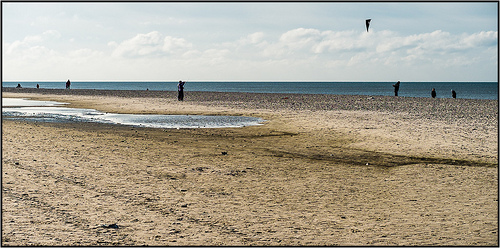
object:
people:
[36, 83, 39, 89]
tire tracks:
[2, 160, 254, 245]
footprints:
[88, 165, 259, 248]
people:
[430, 88, 436, 99]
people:
[15, 83, 22, 88]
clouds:
[2, 5, 496, 78]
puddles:
[2, 96, 269, 129]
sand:
[3, 89, 499, 246]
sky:
[2, 2, 500, 83]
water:
[6, 81, 500, 100]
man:
[66, 79, 71, 89]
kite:
[364, 18, 372, 32]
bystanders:
[431, 88, 457, 99]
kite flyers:
[392, 81, 401, 96]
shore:
[7, 100, 497, 115]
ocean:
[1, 81, 498, 99]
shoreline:
[3, 81, 496, 102]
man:
[177, 80, 186, 102]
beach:
[0, 87, 497, 247]